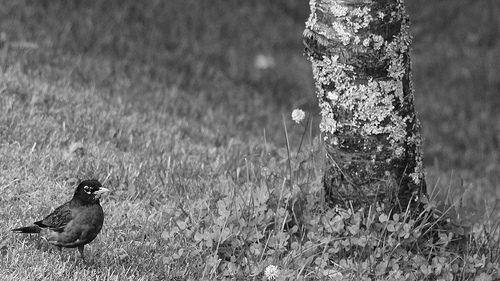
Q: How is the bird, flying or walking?
A: Walking.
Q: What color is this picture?
A: Black and white.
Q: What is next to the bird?
A: A tree.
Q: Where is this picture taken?
A: On a field.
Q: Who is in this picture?
A: Nobody.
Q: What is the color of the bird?
A: Black.